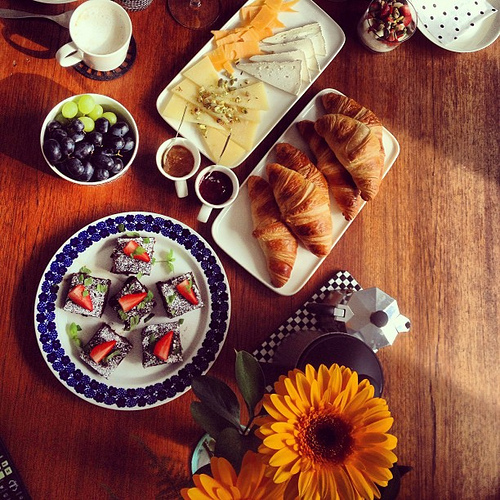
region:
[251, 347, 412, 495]
large yellow flower on table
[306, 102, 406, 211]
large crispy piece of bread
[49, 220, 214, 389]
small chocolate dessert squares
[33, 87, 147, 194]
bowl of purple and green grapes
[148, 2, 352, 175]
white plate with different cheeses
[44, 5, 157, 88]
empty white coffee mug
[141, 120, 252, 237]
small white cups with jam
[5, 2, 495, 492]
table full of delicious foods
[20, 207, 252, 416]
appetizers on a blue and white plate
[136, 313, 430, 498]
yellow daisies in a flower vase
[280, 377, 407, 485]
flower is a sunflower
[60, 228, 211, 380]
strawberry on top of brownie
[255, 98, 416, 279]
croisants on a plate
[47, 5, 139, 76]
white coffee mug on the table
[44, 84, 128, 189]
grapes are green and purple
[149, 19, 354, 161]
three types of cheese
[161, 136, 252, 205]
two dipping sauces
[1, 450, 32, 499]
remote on the table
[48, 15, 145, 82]
coffee cup on a coaster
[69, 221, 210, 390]
powdered sugar on the brownies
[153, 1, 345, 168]
it's cheese. three kinds. with nuts on it.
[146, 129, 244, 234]
two ramekin-type-things, w/ spoons, also condiments inside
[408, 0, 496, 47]
a b+w dotted napkin on a plate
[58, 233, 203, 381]
several little cakey things, w/ slices of strawberries, powder sugar, & an inexplicable green vegetable - no, it's mint. more explicable - on top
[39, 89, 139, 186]
somebody likes two types of grapes at once, green+purple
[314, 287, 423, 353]
top of a stovetop espresso maker, shot from above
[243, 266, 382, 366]
either a checked b/w cloth napkin or a b/w checked little tray beneath espresso maker & pot w/ flower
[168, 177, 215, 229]
the handles, lightly misplaced, on condiment ramekins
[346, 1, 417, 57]
yoghurt, i think, w/ berries+nuts+a tiny bit of maybe chocolate sauce? upper right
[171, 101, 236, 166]
spoon handles, over cheese, look like toothpicks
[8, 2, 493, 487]
A table scene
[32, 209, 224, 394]
A plate of brownies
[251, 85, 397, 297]
Croissants are on this plate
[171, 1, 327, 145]
This plate has cheeses on it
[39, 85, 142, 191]
A bowl of grapes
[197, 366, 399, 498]
Flowers are on the table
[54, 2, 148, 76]
A white mug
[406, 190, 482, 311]
The table is made of wood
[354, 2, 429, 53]
This is a parfait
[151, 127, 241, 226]
These containers have jam in them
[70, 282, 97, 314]
A piece of strawberry.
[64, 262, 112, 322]
A chocolate brownie with sugar.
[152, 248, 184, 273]
Green on the plate.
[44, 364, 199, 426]
Blue trim on the white plate.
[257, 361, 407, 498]
A sun flower.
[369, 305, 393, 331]
Knob of the lid.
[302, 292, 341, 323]
Handle of the jar.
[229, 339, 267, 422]
leaves of the flower.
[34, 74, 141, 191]
A bowl of fruit.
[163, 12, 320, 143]
A cheese platter.